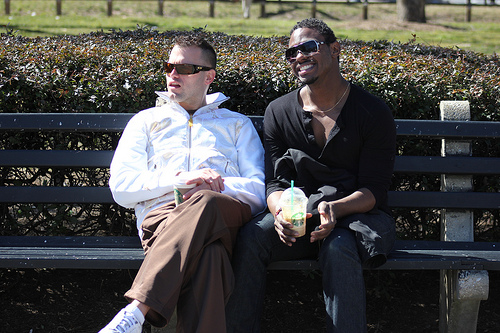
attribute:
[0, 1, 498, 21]
walking path — for walking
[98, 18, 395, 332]
people — here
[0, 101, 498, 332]
bench — wooden, black, here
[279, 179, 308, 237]
container — green, white, here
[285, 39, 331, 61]
sunglasses — black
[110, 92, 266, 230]
jacket — white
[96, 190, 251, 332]
legs — crossed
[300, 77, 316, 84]
goatee — black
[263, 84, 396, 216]
shirt — black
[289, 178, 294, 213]
straw — green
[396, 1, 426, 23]
tree — here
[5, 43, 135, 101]
leaves — green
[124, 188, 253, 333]
pants — brown